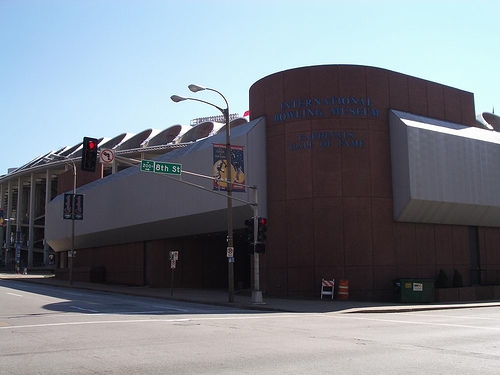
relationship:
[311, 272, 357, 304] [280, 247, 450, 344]
barricade standing against wall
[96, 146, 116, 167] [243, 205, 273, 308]
street sign on pole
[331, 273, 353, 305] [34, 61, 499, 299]
safety cone next to building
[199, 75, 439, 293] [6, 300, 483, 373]
building next to road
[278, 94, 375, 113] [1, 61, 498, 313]
words written on building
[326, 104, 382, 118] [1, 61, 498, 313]
words written on building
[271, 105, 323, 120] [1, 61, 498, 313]
words written on building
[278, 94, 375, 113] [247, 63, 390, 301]
words in corner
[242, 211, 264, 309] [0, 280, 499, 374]
traffic signal on road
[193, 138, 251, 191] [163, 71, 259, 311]
sign on pole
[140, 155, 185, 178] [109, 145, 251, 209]
street sign on metal pole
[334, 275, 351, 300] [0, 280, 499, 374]
safety cone hanging above street road